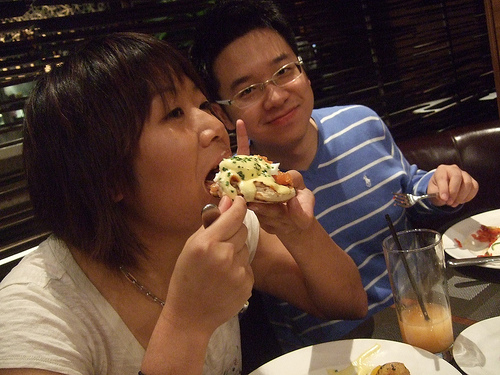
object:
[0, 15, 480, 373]
couple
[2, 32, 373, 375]
person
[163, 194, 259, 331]
hands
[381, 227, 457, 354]
glass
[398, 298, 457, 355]
juice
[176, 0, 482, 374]
man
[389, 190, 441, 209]
fork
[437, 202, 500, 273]
plates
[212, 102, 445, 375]
shirt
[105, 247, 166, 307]
necklace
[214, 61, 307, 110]
glasses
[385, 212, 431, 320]
straw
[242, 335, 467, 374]
plate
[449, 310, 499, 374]
plate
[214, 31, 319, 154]
face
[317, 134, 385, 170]
stripe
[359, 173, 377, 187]
logo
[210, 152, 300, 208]
food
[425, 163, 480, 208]
hands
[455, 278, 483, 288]
reflection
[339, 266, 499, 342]
table